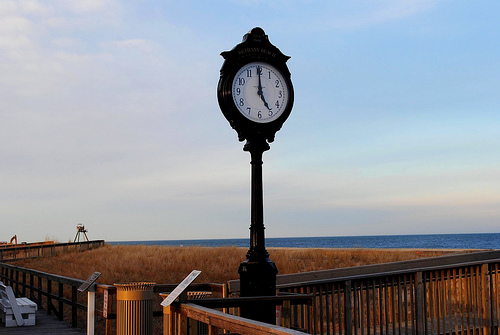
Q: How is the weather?
A: It is clear.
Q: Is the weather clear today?
A: Yes, it is clear.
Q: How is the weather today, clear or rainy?
A: It is clear.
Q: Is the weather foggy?
A: No, it is clear.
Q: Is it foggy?
A: No, it is clear.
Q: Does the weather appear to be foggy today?
A: No, it is clear.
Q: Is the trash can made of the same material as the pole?
A: Yes, both the trash can and the pole are made of metal.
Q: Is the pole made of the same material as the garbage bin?
A: Yes, both the pole and the garbage bin are made of metal.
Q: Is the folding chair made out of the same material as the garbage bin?
A: No, the folding chair is made of wood and the garbage bin is made of metal.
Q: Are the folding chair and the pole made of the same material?
A: No, the folding chair is made of wood and the pole is made of metal.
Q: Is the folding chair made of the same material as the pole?
A: No, the folding chair is made of wood and the pole is made of metal.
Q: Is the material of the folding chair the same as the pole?
A: No, the folding chair is made of wood and the pole is made of metal.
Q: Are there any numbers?
A: Yes, there are numbers.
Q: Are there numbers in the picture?
A: Yes, there are numbers.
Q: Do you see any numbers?
A: Yes, there are numbers.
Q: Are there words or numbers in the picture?
A: Yes, there are numbers.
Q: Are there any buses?
A: No, there are no buses.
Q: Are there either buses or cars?
A: No, there are no buses or cars.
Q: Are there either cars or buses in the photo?
A: No, there are no buses or cars.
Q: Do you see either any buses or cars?
A: No, there are no buses or cars.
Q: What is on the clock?
A: The numbers are on the clock.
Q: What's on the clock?
A: The numbers are on the clock.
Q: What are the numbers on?
A: The numbers are on the clock.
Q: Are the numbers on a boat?
A: No, the numbers are on a clock.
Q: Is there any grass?
A: Yes, there is grass.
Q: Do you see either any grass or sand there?
A: Yes, there is grass.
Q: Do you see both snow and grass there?
A: No, there is grass but no snow.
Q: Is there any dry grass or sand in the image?
A: Yes, there is dry grass.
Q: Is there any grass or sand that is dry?
A: Yes, the grass is dry.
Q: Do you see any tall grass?
A: Yes, there is tall grass.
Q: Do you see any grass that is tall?
A: Yes, there is grass that is tall.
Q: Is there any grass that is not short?
A: Yes, there is tall grass.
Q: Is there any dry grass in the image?
A: Yes, there is dry grass.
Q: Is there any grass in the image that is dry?
A: Yes, there is grass that is dry.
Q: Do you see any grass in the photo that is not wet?
A: Yes, there is dry grass.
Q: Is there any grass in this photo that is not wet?
A: Yes, there is dry grass.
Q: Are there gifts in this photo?
A: No, there are no gifts.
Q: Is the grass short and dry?
A: No, the grass is dry but tall.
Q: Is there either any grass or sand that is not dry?
A: No, there is grass but it is dry.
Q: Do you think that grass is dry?
A: Yes, the grass is dry.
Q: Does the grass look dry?
A: Yes, the grass is dry.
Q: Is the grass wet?
A: No, the grass is dry.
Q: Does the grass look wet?
A: No, the grass is dry.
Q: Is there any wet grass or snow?
A: No, there is grass but it is dry.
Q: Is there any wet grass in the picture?
A: No, there is grass but it is dry.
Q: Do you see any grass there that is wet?
A: No, there is grass but it is dry.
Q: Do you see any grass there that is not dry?
A: No, there is grass but it is dry.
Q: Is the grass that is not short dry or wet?
A: The grass is dry.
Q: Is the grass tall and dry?
A: Yes, the grass is tall and dry.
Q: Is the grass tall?
A: Yes, the grass is tall.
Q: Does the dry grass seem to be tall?
A: Yes, the grass is tall.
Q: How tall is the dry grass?
A: The grass is tall.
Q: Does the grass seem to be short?
A: No, the grass is tall.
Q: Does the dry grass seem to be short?
A: No, the grass is tall.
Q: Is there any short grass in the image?
A: No, there is grass but it is tall.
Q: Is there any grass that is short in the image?
A: No, there is grass but it is tall.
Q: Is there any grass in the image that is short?
A: No, there is grass but it is tall.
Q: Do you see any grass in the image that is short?
A: No, there is grass but it is tall.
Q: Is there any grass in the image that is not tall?
A: No, there is grass but it is tall.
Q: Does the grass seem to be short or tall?
A: The grass is tall.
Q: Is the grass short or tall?
A: The grass is tall.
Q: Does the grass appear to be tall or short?
A: The grass is tall.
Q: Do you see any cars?
A: No, there are no cars.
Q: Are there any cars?
A: No, there are no cars.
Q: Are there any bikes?
A: No, there are no bikes.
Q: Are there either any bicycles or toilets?
A: No, there are no bicycles or toilets.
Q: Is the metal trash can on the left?
A: Yes, the trash can is on the left of the image.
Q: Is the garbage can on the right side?
A: No, the garbage can is on the left of the image.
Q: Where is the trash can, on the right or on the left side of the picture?
A: The trash can is on the left of the image.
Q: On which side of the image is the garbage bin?
A: The garbage bin is on the left of the image.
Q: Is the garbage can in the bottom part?
A: Yes, the garbage can is in the bottom of the image.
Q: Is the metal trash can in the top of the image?
A: No, the garbage can is in the bottom of the image.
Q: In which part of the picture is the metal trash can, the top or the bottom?
A: The trash bin is in the bottom of the image.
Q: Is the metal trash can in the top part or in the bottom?
A: The trash bin is in the bottom of the image.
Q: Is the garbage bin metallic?
A: Yes, the garbage bin is metallic.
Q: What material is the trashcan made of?
A: The trashcan is made of metal.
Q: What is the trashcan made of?
A: The trashcan is made of metal.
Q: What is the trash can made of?
A: The trashcan is made of metal.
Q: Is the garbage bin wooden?
A: No, the garbage bin is metallic.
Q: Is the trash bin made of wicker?
A: No, the trash bin is made of metal.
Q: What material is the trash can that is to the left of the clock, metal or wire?
A: The trash bin is made of metal.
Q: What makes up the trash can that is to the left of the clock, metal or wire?
A: The trash bin is made of metal.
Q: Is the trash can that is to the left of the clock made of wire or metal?
A: The trash bin is made of metal.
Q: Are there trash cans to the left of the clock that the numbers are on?
A: Yes, there is a trash can to the left of the clock.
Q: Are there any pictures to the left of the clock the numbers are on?
A: No, there is a trash can to the left of the clock.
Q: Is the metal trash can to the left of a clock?
A: Yes, the trashcan is to the left of a clock.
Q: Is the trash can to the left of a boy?
A: No, the trash can is to the left of a clock.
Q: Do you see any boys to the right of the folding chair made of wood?
A: No, there is a trash can to the right of the folding chair.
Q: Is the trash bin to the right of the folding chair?
A: Yes, the trash bin is to the right of the folding chair.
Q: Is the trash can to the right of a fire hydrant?
A: No, the trash can is to the right of the folding chair.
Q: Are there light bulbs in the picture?
A: No, there are no light bulbs.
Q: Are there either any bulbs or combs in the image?
A: No, there are no bulbs or combs.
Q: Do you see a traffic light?
A: No, there are no traffic lights.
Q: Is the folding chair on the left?
A: Yes, the folding chair is on the left of the image.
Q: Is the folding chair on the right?
A: No, the folding chair is on the left of the image.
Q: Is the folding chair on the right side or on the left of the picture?
A: The folding chair is on the left of the image.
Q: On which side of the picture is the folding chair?
A: The folding chair is on the left of the image.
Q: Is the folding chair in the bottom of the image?
A: Yes, the folding chair is in the bottom of the image.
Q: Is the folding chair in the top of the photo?
A: No, the folding chair is in the bottom of the image.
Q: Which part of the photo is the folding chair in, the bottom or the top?
A: The folding chair is in the bottom of the image.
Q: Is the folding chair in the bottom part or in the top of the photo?
A: The folding chair is in the bottom of the image.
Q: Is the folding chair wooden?
A: Yes, the folding chair is wooden.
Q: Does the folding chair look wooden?
A: Yes, the folding chair is wooden.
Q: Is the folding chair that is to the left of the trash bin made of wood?
A: Yes, the folding chair is made of wood.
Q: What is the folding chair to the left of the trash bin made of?
A: The folding chair is made of wood.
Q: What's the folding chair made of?
A: The folding chair is made of wood.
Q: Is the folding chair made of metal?
A: No, the folding chair is made of wood.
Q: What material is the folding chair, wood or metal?
A: The folding chair is made of wood.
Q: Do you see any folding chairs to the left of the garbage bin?
A: Yes, there is a folding chair to the left of the garbage bin.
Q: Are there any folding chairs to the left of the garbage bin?
A: Yes, there is a folding chair to the left of the garbage bin.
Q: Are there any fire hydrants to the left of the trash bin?
A: No, there is a folding chair to the left of the trash bin.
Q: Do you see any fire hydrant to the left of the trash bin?
A: No, there is a folding chair to the left of the trash bin.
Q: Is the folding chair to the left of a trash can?
A: Yes, the folding chair is to the left of a trash can.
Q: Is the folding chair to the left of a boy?
A: No, the folding chair is to the left of a trash can.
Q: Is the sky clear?
A: Yes, the sky is clear.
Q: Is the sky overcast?
A: No, the sky is clear.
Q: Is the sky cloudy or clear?
A: The sky is clear.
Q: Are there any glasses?
A: No, there are no glasses.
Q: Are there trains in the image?
A: No, there are no trains.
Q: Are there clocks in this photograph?
A: Yes, there is a clock.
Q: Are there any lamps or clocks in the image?
A: Yes, there is a clock.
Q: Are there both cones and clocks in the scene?
A: No, there is a clock but no cones.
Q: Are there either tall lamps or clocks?
A: Yes, there is a tall clock.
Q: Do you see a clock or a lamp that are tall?
A: Yes, the clock is tall.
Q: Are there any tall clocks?
A: Yes, there is a tall clock.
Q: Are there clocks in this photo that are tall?
A: Yes, there is a clock that is tall.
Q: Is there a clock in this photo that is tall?
A: Yes, there is a clock that is tall.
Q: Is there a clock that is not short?
A: Yes, there is a tall clock.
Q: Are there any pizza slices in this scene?
A: No, there are no pizza slices.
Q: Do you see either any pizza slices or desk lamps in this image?
A: No, there are no pizza slices or desk lamps.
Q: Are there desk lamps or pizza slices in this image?
A: No, there are no pizza slices or desk lamps.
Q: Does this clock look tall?
A: Yes, the clock is tall.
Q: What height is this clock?
A: The clock is tall.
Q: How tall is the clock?
A: The clock is tall.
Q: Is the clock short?
A: No, the clock is tall.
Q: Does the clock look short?
A: No, the clock is tall.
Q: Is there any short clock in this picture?
A: No, there is a clock but it is tall.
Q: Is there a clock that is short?
A: No, there is a clock but it is tall.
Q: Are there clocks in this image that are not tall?
A: No, there is a clock but it is tall.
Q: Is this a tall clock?
A: Yes, this is a tall clock.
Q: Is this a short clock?
A: No, this is a tall clock.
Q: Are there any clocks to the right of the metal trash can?
A: Yes, there is a clock to the right of the trash bin.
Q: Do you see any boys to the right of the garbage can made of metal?
A: No, there is a clock to the right of the garbage bin.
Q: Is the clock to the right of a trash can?
A: Yes, the clock is to the right of a trash can.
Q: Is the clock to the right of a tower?
A: No, the clock is to the right of a trash can.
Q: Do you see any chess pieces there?
A: No, there are no chess pieces.